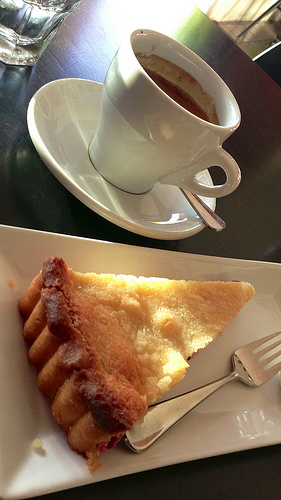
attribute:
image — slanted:
[2, 4, 280, 500]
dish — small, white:
[26, 76, 216, 240]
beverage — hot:
[88, 28, 240, 198]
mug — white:
[87, 29, 241, 196]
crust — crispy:
[15, 257, 131, 472]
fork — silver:
[123, 331, 279, 454]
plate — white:
[27, 76, 215, 242]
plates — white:
[5, 75, 279, 498]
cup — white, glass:
[86, 27, 243, 199]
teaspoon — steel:
[178, 187, 237, 232]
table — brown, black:
[9, 6, 276, 266]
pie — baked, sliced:
[18, 256, 255, 472]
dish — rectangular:
[0, 224, 280, 499]